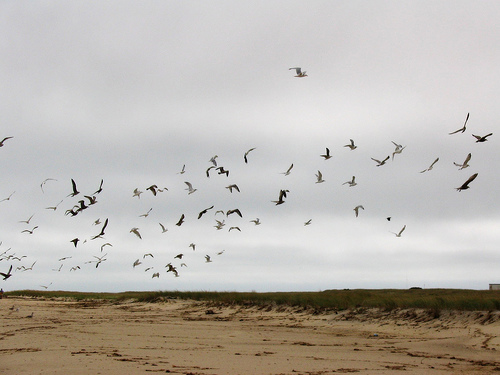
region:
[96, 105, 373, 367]
the birds are flying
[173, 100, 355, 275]
the birds are flying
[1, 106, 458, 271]
many birds flying in sky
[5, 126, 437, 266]
many birds fly over beach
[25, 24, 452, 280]
skies are grey at beach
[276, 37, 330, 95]
one bird flying higher than the others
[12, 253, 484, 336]
grass in background of photograph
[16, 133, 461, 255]
many black birds in sky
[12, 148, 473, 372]
photo of birds flying at beach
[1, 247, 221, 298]
several birds flying close to ground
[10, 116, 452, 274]
flock of birds in photo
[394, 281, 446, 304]
something on grass in background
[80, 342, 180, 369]
footprints in the sand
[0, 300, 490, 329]
grass on the edge of a sandy beach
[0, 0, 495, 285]
a cloudy gray sky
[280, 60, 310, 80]
one bird soaring above the others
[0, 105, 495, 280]
a flock of birds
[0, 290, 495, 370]
a beach below a flock of birds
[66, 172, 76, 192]
a wing pointing upward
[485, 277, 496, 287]
a building in the distance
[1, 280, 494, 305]
a green grassy field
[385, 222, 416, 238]
a bird with both wings uplifted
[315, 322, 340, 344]
part of a beach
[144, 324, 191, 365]
part of a sandy terrain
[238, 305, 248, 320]
edge of a beach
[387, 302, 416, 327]
edge of a plantation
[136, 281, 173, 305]
a small hill on the surface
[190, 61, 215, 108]
part of the sky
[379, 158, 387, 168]
a bird in air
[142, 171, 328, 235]
group of birds in air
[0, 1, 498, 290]
sky is gray and cloudy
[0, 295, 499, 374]
brown sand under gray sky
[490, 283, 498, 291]
building in distance beyond sand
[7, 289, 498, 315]
grass beyond sand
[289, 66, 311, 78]
light colored bird is flying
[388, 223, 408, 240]
bird against sky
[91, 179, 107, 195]
bird with outstretched wings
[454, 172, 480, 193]
dark bird against gray sky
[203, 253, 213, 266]
bird flying over sand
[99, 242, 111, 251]
sand under bird